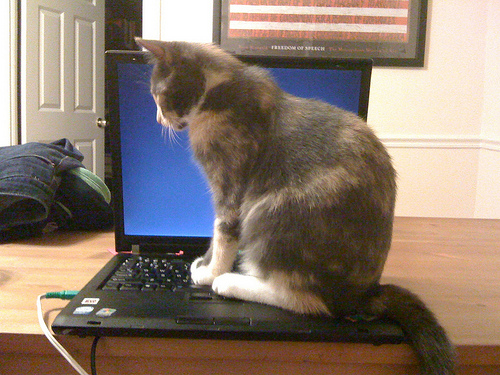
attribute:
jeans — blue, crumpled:
[4, 139, 117, 244]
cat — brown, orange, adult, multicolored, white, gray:
[121, 27, 450, 332]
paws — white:
[185, 255, 238, 290]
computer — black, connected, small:
[39, 35, 412, 338]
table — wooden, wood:
[14, 212, 492, 365]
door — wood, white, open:
[20, 4, 110, 143]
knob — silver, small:
[95, 116, 113, 130]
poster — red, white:
[205, 3, 433, 72]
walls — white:
[381, 77, 494, 216]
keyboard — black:
[83, 252, 240, 293]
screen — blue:
[111, 62, 360, 230]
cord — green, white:
[46, 287, 79, 301]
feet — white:
[191, 256, 284, 307]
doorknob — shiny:
[96, 115, 115, 137]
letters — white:
[159, 268, 177, 282]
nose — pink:
[152, 113, 165, 125]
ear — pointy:
[128, 34, 173, 65]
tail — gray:
[370, 283, 461, 371]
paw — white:
[192, 267, 218, 292]